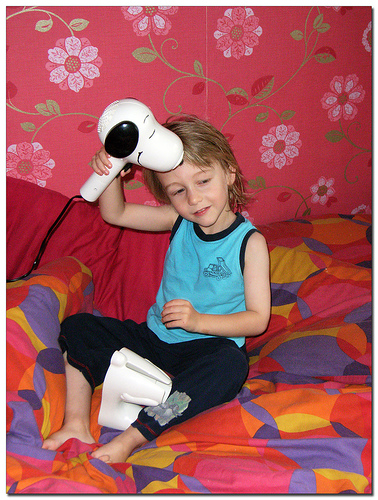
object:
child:
[42, 115, 271, 467]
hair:
[142, 115, 250, 213]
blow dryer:
[79, 98, 184, 204]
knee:
[58, 313, 88, 347]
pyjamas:
[57, 312, 248, 443]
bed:
[7, 177, 377, 500]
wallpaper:
[6, 7, 373, 228]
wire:
[7, 194, 82, 283]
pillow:
[6, 175, 171, 324]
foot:
[41, 425, 96, 450]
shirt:
[146, 211, 263, 348]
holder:
[98, 346, 172, 432]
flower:
[45, 36, 103, 94]